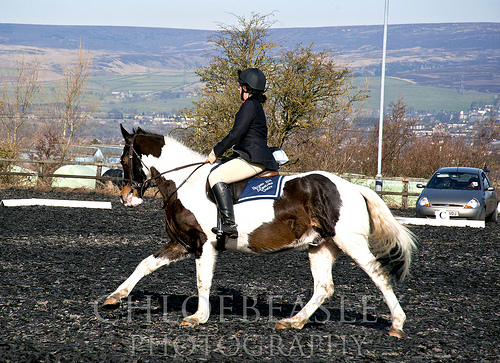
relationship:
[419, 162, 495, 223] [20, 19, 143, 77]
car in background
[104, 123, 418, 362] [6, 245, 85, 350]
horse in field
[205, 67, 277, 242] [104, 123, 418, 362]
person on horse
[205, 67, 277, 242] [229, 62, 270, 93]
person wearing helmet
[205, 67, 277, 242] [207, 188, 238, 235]
person wearing boots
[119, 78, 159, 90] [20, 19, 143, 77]
grass in background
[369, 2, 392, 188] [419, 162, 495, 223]
pole by car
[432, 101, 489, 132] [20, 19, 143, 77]
houses are in background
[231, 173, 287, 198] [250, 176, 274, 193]
blue blanket with white letters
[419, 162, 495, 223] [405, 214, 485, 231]
car behind curb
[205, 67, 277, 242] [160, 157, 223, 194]
person on reign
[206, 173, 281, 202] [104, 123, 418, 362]
saddle on horse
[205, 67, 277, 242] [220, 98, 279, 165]
person wearing jacket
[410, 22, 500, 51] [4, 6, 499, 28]
hill on horizon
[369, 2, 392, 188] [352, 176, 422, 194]
pole behind fence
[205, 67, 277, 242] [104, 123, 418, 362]
person riding horse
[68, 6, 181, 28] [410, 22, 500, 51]
sky above hill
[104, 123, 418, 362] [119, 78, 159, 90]
horse on grass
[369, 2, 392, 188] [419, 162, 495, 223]
pole behind car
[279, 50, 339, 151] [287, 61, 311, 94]
tree has leaves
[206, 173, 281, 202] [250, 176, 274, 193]
saddle has white letters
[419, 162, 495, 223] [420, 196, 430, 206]
car with lights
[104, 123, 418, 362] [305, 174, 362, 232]
horse with brown and white hair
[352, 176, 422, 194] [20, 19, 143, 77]
fence in background